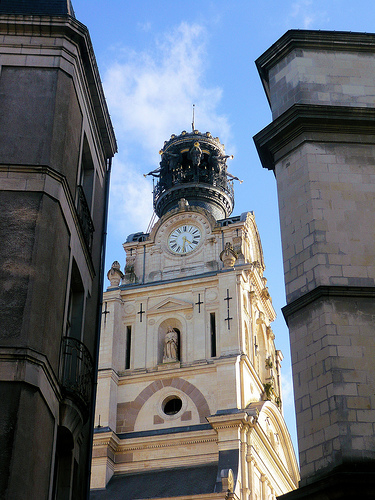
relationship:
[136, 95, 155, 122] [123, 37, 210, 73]
see through clouds in blue sky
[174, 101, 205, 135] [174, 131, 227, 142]
pole coming out of top of roof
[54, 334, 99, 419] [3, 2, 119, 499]
rail on building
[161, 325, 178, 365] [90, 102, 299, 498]
statue in alcove of building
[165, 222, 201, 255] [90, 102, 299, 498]
clock on building